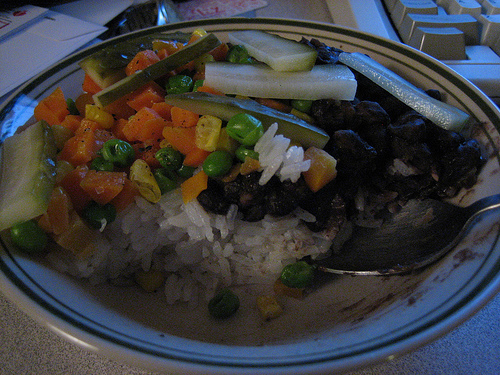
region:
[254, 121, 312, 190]
grains of white rice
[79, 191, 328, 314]
grains of white rice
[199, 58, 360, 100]
spear of a pickle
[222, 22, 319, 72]
spear of a pickle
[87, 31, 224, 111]
spear of a pickle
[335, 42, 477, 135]
spear of a pickle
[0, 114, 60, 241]
spear of a pickle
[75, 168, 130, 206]
small piece of carrot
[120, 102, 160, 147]
small piece of carrot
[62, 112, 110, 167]
small piece of carrot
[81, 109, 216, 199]
A mix of veggies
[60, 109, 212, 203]
Carrots on the rice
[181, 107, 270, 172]
peas and corn on the dish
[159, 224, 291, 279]
white sticky rice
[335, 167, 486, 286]
a spoon on the bowl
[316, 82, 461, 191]
beeans in the bowl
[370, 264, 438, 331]
beans scraped on the side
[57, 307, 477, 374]
the trim is black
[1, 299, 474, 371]
a bowl on the counter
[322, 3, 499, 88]
a keyboard in the corner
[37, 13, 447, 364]
a plate of food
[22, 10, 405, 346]
vegetables on top of rice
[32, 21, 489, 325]
a plate of vegetables and rice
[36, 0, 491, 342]
a plate of beans and vegetables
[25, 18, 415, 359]
corn carrots peas and rice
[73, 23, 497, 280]
a plate with rice at the bottom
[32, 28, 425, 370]
a plate with a green rim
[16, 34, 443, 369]
a plate with a silver spoon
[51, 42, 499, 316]
a plate on a table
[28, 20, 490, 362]
a plate of food on the table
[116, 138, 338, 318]
small pieces of white rice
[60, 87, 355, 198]
small cut up pieces of carrot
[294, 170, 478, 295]
silver spoon on a plate of food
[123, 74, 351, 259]
pieces of green bean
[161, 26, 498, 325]
black beans on a plate of white rice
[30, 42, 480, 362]
a plate of vegetarian food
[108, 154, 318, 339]
a plate of small pieces of corn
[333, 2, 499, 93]
keyboard next to a plate of food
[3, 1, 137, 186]
letter next to a plate of food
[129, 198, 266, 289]
white rice in the bottom of a bowl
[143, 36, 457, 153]
sliced pieces of cucumber in a bowl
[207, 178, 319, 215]
black beans in a bowl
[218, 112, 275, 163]
fresh green peas in a bowl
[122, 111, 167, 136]
diced peppers carrots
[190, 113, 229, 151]
yellow corn kernels in a bowl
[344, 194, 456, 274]
a silver spoon with black bean juice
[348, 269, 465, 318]
black bean juice smeared on the inside of a bowl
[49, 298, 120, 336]
a green line around the rim of a bowl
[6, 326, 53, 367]
a gray and white speckled counter top